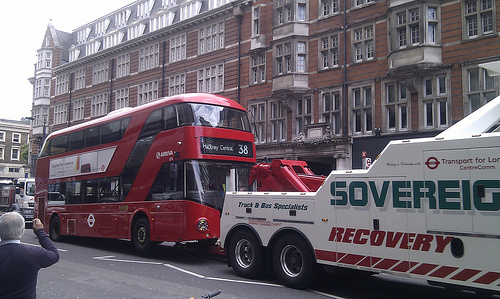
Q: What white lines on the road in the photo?
A: White lines in the street.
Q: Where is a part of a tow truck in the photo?
A: Front of the red bus.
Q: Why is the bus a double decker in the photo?
A: Sightseeing bus.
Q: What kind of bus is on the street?
A: Double decker.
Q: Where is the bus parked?
A: On the street.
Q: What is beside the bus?
A: Building.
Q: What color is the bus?
A: Red.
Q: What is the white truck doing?
A: Towing the bus.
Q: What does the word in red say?
A: Recovery.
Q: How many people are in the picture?
A: 1.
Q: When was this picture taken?
A: Daytime.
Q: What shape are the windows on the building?
A: Square.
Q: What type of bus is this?
A: Double decker.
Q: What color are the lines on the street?
A: White.